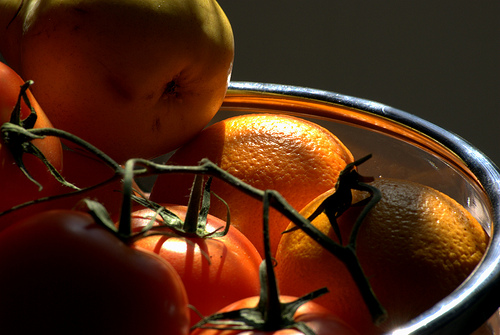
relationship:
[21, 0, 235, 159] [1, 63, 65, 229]
apple beside tomato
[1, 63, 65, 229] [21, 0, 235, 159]
tomato beside apple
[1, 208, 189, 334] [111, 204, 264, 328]
tomato by tomato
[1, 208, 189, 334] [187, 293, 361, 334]
tomato by tomato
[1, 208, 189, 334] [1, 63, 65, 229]
tomato by tomato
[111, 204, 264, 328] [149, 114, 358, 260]
tomato by orange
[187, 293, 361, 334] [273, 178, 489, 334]
tomato by orange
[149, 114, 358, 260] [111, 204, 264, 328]
orange by tomato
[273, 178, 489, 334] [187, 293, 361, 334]
orange by tomato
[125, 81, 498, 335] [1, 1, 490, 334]
bowl has produce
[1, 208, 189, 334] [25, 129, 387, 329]
tomato on vine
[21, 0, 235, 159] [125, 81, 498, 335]
apple on bowl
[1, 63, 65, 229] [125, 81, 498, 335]
tomato in bowl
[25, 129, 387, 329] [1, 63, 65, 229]
vine touching tomato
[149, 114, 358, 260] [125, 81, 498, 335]
orange in bowl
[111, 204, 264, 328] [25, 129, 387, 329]
tomato on vine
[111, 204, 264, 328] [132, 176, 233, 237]
tomato has leaf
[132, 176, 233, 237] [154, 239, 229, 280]
leaf casting shadow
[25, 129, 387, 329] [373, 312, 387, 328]
vine has tip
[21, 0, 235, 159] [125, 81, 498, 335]
apple in bowl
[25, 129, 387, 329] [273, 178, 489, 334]
vine touching orange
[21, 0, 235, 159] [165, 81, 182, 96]
apple has stem